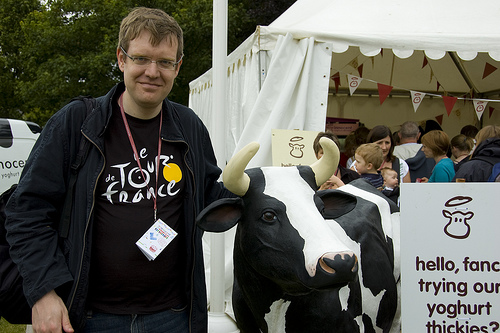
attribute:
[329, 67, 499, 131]
flags — red, white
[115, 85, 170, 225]
lanyard — red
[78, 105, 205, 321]
shirt — white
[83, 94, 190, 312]
shirt — man's shirt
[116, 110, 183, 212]
lanyard — red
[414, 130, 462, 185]
woman — wearing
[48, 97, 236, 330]
sweater — black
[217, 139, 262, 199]
horn — white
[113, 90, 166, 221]
lanyard — red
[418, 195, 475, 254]
head — baby's head, little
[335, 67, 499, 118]
banner — red and white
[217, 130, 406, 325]
plastic cow — black and white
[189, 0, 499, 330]
tent — white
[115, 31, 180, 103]
face — man's face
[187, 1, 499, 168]
tent — white